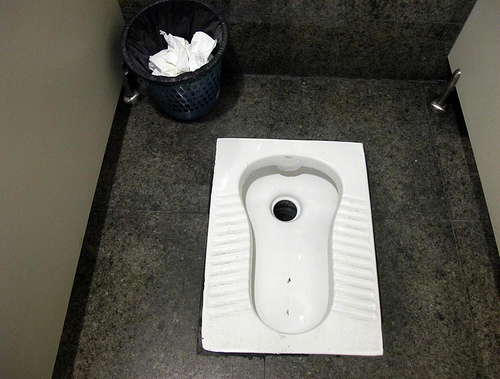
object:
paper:
[148, 30, 218, 78]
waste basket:
[120, 5, 227, 120]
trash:
[147, 28, 218, 77]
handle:
[124, 90, 139, 104]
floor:
[64, 69, 453, 379]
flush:
[199, 138, 384, 356]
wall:
[449, 0, 500, 241]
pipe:
[429, 68, 461, 114]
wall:
[0, 0, 120, 379]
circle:
[273, 200, 298, 222]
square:
[198, 138, 384, 356]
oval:
[237, 155, 343, 335]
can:
[112, 10, 242, 79]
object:
[429, 68, 462, 115]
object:
[122, 71, 139, 105]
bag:
[120, 0, 227, 122]